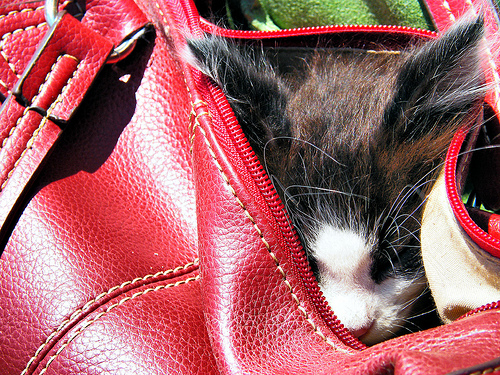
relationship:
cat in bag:
[171, 16, 464, 334] [0, 0, 500, 374]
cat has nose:
[171, 16, 464, 334] [331, 311, 390, 339]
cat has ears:
[171, 16, 464, 334] [183, 11, 489, 114]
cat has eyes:
[171, 16, 464, 334] [301, 235, 415, 280]